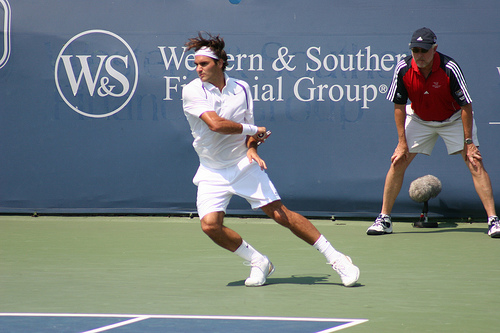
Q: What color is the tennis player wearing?
A: White.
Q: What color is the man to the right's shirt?
A: Red.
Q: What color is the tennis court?
A: Blue.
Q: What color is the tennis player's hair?
A: Brown.